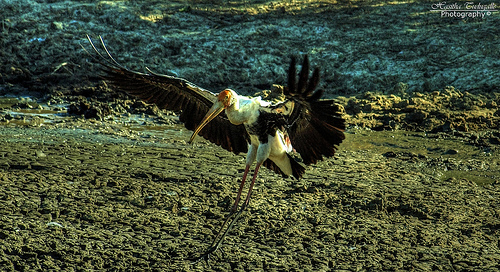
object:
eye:
[225, 95, 229, 99]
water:
[0, 95, 179, 131]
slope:
[1, 1, 495, 97]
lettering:
[431, 0, 493, 19]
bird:
[77, 41, 345, 268]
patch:
[267, 105, 293, 115]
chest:
[224, 112, 251, 124]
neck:
[225, 101, 251, 124]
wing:
[269, 55, 347, 167]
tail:
[279, 52, 346, 165]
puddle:
[430, 167, 497, 185]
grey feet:
[182, 244, 227, 268]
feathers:
[280, 52, 347, 165]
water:
[344, 129, 494, 182]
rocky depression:
[338, 86, 498, 132]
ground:
[6, 167, 498, 269]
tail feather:
[306, 65, 321, 102]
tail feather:
[310, 88, 326, 101]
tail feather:
[296, 53, 308, 101]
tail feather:
[286, 50, 296, 96]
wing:
[87, 36, 245, 156]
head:
[215, 87, 239, 109]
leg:
[213, 160, 261, 247]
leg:
[211, 162, 251, 245]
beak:
[188, 100, 224, 145]